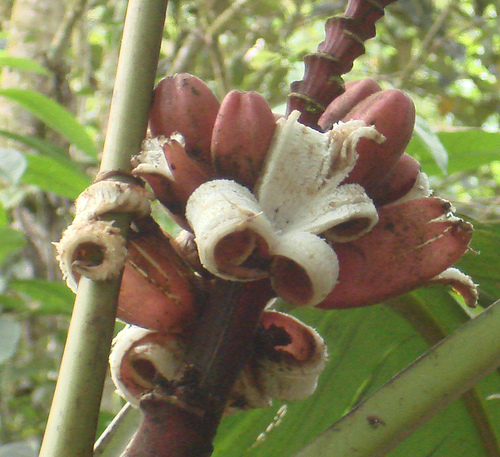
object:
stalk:
[118, 0, 392, 455]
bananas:
[84, 116, 344, 396]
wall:
[434, 122, 462, 146]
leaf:
[8, 59, 88, 226]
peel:
[178, 110, 386, 316]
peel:
[64, 126, 476, 391]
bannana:
[83, 66, 474, 379]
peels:
[168, 149, 365, 304]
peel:
[67, 199, 149, 267]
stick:
[76, 15, 114, 433]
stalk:
[273, 15, 389, 132]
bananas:
[320, 64, 426, 175]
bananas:
[133, 52, 218, 149]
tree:
[83, 6, 450, 454]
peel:
[213, 129, 358, 277]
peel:
[224, 304, 330, 411]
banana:
[47, 70, 480, 412]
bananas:
[51, 133, 377, 401]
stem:
[40, 1, 170, 453]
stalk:
[40, 0, 167, 454]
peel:
[222, 360, 272, 412]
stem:
[122, 1, 384, 455]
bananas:
[93, 81, 473, 391]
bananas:
[108, 98, 318, 315]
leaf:
[1, 88, 102, 159]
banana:
[145, 69, 215, 167]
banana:
[208, 86, 273, 179]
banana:
[330, 87, 417, 179]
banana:
[60, 175, 204, 335]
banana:
[124, 132, 216, 211]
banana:
[104, 321, 204, 426]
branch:
[122, 0, 387, 453]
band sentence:
[170, 78, 475, 388]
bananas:
[90, 60, 482, 328]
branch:
[41, 1, 169, 455]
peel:
[184, 108, 379, 307]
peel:
[157, 138, 193, 170]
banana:
[195, 307, 338, 412]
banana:
[197, 107, 466, 407]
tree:
[46, 4, 402, 416]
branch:
[388, 14, 444, 83]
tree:
[2, 0, 489, 454]